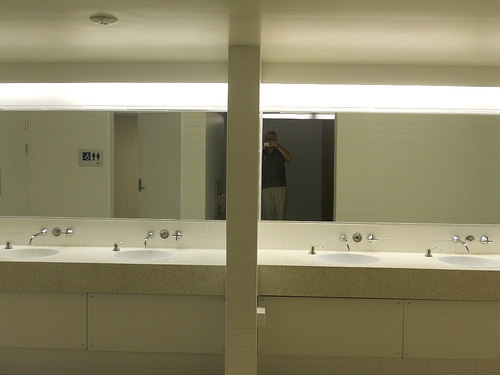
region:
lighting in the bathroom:
[0, 83, 232, 108]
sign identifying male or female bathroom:
[70, 145, 110, 166]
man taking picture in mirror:
[261, 122, 292, 217]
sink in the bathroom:
[311, 244, 373, 267]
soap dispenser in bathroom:
[303, 237, 323, 259]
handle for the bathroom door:
[133, 176, 147, 199]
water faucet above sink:
[139, 227, 153, 248]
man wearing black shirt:
[263, 150, 287, 184]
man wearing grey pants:
[259, 192, 295, 220]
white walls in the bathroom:
[336, 114, 490, 218]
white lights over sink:
[272, 83, 497, 115]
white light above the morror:
[268, 78, 498, 118]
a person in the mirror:
[257, 130, 300, 216]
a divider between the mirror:
[221, 33, 266, 370]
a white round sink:
[308, 251, 392, 263]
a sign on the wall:
[77, 149, 101, 169]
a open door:
[112, 111, 182, 215]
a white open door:
[113, 109, 184, 216]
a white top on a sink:
[266, 246, 306, 291]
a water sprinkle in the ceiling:
[86, 8, 115, 32]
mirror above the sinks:
[2, 110, 499, 224]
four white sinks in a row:
[2, 220, 496, 271]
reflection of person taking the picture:
[254, 130, 295, 218]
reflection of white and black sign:
[77, 145, 99, 168]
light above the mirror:
[5, 78, 497, 120]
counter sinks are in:
[2, 260, 499, 366]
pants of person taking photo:
[262, 188, 284, 216]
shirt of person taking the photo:
[260, 145, 285, 182]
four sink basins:
[2, 237, 491, 271]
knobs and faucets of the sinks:
[19, 223, 493, 259]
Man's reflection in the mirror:
[261, 128, 296, 220]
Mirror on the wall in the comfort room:
[0, 82, 496, 222]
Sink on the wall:
[300, 232, 385, 267]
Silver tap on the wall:
[365, 233, 379, 243]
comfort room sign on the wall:
[72, 146, 107, 168]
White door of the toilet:
[132, 111, 187, 221]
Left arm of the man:
[268, 140, 291, 162]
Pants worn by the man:
[260, 185, 288, 220]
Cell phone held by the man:
[262, 141, 273, 148]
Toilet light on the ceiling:
[0, 81, 499, 111]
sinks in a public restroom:
[7, 82, 495, 356]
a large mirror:
[3, 106, 495, 241]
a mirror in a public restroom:
[2, 106, 497, 231]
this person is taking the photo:
[247, 113, 309, 218]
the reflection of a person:
[251, 99, 308, 236]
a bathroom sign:
[68, 142, 109, 172]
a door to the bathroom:
[99, 80, 200, 240]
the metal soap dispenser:
[307, 229, 344, 263]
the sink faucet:
[141, 223, 165, 258]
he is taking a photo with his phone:
[243, 119, 318, 226]